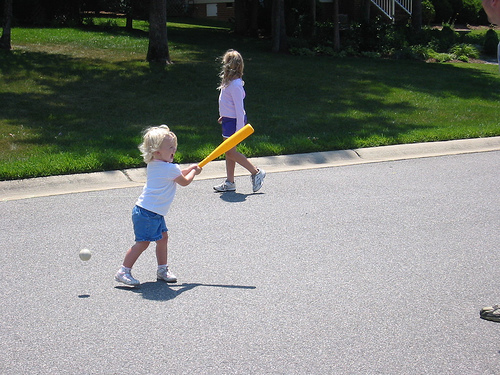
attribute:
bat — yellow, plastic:
[195, 117, 257, 172]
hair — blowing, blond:
[228, 53, 233, 69]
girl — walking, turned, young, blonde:
[206, 50, 253, 202]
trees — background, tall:
[234, 0, 310, 63]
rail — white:
[373, 3, 395, 20]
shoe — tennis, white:
[211, 175, 238, 192]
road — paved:
[337, 191, 394, 238]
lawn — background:
[57, 55, 119, 90]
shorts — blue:
[226, 122, 235, 134]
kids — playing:
[126, 77, 238, 258]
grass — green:
[44, 62, 97, 97]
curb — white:
[323, 137, 377, 164]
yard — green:
[315, 57, 404, 135]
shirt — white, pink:
[217, 92, 240, 115]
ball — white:
[78, 249, 96, 262]